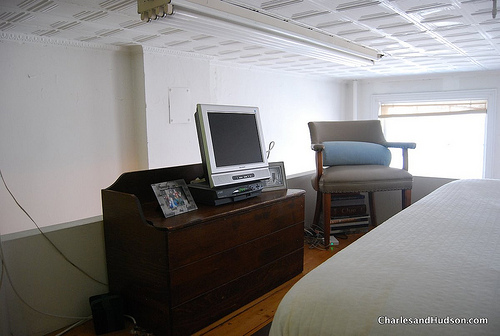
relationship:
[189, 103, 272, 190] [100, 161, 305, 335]
television on top of dresser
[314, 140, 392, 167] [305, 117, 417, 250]
pillow on top of chair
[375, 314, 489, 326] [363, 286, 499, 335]
name in corner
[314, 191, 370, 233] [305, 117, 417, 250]
books underneath chair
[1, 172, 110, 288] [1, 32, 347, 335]
wire coming down wall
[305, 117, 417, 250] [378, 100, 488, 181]
chair next to window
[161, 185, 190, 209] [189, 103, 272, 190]
picture next to television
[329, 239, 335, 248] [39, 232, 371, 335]
light above floor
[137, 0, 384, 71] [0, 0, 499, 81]
light fixture hanging on ceiling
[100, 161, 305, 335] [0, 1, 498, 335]
dresser inside of room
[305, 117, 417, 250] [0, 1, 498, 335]
chair inside of room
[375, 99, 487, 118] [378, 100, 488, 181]
blinds above window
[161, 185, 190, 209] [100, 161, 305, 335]
picture on top of dresser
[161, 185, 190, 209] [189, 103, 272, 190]
picture to left of television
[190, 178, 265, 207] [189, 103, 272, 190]
cable box underneath television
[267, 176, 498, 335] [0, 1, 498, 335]
bed inside of room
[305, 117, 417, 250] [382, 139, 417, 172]
chair has left armrest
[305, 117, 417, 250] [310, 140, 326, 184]
chair has right armrest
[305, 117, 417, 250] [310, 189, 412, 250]
chair has legs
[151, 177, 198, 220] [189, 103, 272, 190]
picture frame on left of television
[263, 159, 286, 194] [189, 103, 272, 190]
picture frame on right of television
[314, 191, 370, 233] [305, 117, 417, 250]
books stacked under chair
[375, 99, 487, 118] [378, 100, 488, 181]
blinds raised on window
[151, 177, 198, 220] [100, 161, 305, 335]
picture frame on top of dresser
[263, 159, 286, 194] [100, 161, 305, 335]
picture frame on top of dresser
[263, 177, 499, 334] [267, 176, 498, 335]
comforter on top of bed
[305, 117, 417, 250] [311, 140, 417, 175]
chair has armrests